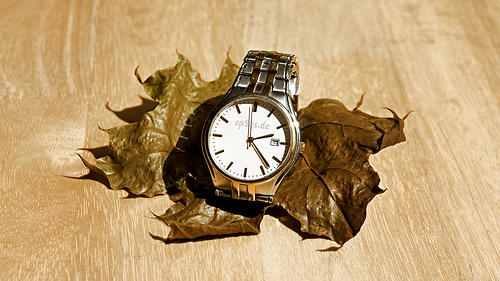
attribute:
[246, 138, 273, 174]
hand — second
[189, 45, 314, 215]
watch — wrist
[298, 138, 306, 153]
winder — small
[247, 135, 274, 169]
hands — black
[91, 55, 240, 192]
leaf — green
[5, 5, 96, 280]
platform — brown, wooden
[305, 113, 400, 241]
leaf — green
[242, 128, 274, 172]
hands — clock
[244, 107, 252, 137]
arm — small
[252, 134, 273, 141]
arm — small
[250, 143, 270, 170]
arm — small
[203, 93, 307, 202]
watch — wrist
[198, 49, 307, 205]
watch — silvertone, grey, wrist, gold, silver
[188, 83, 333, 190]
clock — face, white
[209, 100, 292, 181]
face — white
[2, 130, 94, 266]
surface — light brown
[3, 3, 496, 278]
table — wood, big